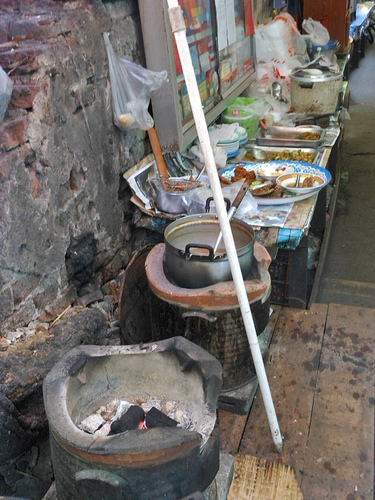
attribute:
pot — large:
[286, 62, 344, 117]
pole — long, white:
[163, 0, 289, 459]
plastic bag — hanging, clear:
[96, 28, 172, 139]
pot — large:
[295, 70, 341, 113]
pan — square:
[253, 119, 331, 151]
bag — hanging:
[69, 26, 183, 162]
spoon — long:
[208, 169, 255, 254]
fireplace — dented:
[44, 330, 236, 497]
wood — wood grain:
[315, 318, 372, 496]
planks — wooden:
[210, 293, 372, 498]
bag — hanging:
[97, 27, 173, 137]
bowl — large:
[231, 160, 327, 198]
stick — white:
[161, 4, 301, 461]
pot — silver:
[172, 220, 255, 279]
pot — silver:
[164, 195, 255, 283]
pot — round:
[162, 189, 260, 289]